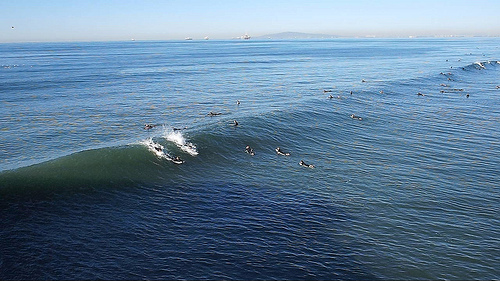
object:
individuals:
[243, 144, 256, 156]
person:
[417, 92, 425, 97]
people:
[297, 159, 316, 169]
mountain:
[248, 27, 500, 39]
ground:
[370, 120, 407, 181]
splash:
[136, 134, 165, 157]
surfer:
[153, 147, 163, 153]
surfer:
[170, 126, 186, 131]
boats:
[141, 139, 187, 165]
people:
[143, 123, 157, 130]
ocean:
[0, 40, 500, 278]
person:
[235, 99, 242, 105]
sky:
[0, 0, 497, 41]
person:
[165, 154, 184, 164]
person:
[229, 120, 239, 126]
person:
[244, 144, 256, 155]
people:
[275, 147, 292, 157]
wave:
[1, 58, 500, 199]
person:
[350, 114, 364, 121]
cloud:
[0, 0, 499, 43]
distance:
[0, 31, 500, 44]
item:
[10, 26, 16, 29]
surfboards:
[277, 153, 291, 157]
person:
[153, 142, 162, 151]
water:
[0, 42, 499, 280]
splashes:
[161, 127, 183, 142]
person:
[236, 99, 242, 106]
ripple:
[0, 61, 500, 278]